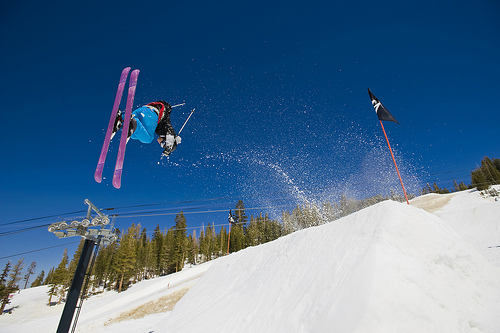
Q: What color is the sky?
A: Blue.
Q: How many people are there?
A: One.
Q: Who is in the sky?
A: The skier.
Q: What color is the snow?
A: White.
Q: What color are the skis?
A: Pink.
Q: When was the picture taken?
A: Daytime.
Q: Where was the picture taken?
A: A ski obstacle course.